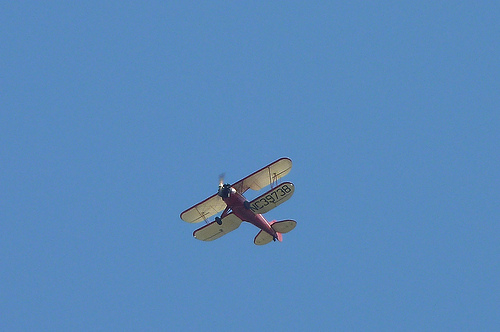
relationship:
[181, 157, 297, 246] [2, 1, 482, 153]
biplane flyng in blue sky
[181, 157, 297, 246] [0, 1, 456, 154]
biplane flyng in sky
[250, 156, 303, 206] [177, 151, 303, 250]
wings are attached to plane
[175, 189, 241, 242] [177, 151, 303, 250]
white wings are attached to plane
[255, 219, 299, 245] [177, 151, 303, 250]
tail are attached to plane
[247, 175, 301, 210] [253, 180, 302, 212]
number attached to wing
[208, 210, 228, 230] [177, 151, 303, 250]
wheel attached to plane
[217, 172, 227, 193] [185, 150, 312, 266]
propeller attached to plane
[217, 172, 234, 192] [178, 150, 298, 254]
propeller attached to airplane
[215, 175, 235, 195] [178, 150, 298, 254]
engine attached to airplane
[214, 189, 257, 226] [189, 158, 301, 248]
wheels are attached to airplane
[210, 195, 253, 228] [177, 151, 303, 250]
landing gear on belly of plane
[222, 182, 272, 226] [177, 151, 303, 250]
body of plane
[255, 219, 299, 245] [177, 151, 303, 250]
tail of plane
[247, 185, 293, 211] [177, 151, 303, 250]
number on plane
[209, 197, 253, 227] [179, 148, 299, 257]
wheels on plane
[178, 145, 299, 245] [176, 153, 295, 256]
wings on plane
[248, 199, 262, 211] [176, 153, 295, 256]
nc on plane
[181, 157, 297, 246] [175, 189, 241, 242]
biplane with white wings